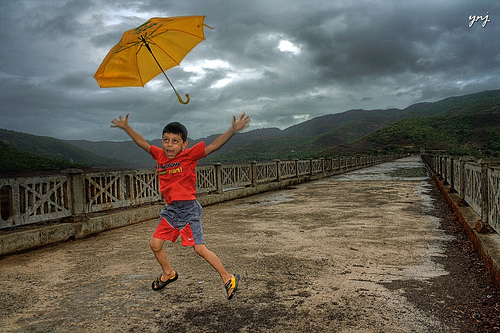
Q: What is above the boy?
A: Umbrella.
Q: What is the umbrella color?
A: Yellow.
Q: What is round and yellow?
A: Umbrella.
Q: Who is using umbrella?
A: The boy.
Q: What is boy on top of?
A: The bridge.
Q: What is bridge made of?
A: Concrete.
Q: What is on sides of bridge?
A: Safety fence.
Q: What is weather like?
A: Dark and stormy.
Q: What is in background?
A: Trees and hills.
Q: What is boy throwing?
A: Umbrella.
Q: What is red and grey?
A: Boy's shorts.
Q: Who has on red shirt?
A: The boy.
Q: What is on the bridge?
A: The boy.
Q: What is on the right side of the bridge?
A: The rails.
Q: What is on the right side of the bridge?
A: The rails.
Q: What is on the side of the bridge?
A: The gravel.